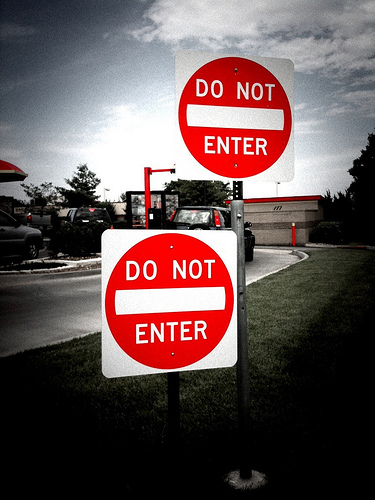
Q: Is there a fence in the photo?
A: No, there are no fences.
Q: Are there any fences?
A: No, there are no fences.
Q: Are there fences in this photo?
A: No, there are no fences.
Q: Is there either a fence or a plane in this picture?
A: No, there are no fences or airplanes.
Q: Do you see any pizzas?
A: No, there are no pizzas.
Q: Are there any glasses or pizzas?
A: No, there are no pizzas or glasses.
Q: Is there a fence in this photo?
A: No, there are no fences.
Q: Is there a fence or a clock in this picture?
A: No, there are no fences or clocks.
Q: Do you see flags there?
A: No, there are no flags.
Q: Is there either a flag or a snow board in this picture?
A: No, there are no flags or snowboards.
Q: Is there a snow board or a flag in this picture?
A: No, there are no flags or snowboards.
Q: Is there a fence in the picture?
A: No, there are no fences.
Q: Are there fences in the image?
A: No, there are no fences.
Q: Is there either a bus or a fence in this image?
A: No, there are no fences or buses.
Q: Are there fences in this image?
A: No, there are no fences.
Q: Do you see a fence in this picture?
A: No, there are no fences.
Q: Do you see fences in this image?
A: No, there are no fences.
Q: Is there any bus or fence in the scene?
A: No, there are no fences or buses.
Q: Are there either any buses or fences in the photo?
A: No, there are no fences or buses.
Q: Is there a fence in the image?
A: No, there are no fences.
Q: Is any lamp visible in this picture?
A: No, there are no lamps.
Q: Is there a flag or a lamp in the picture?
A: No, there are no lamps or flags.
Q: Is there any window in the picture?
A: Yes, there are windows.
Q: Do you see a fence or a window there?
A: Yes, there are windows.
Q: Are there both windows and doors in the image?
A: No, there are windows but no doors.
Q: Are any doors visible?
A: No, there are no doors.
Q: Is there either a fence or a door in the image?
A: No, there are no doors or fences.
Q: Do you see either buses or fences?
A: No, there are no fences or buses.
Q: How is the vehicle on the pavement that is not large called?
A: The vehicle is a car.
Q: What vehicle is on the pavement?
A: The vehicle is a car.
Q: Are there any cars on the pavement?
A: Yes, there is a car on the pavement.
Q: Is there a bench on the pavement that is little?
A: No, there is a car on the pavement.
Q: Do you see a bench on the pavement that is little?
A: No, there is a car on the pavement.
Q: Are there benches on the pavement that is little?
A: No, there is a car on the pavement.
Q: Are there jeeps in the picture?
A: No, there are no jeeps.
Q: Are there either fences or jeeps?
A: No, there are no jeeps or fences.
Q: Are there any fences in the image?
A: No, there are no fences.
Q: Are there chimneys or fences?
A: No, there are no fences or chimneys.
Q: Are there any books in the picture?
A: No, there are no books.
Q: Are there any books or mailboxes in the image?
A: No, there are no books or mailboxes.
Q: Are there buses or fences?
A: No, there are no fences or buses.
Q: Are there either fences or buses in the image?
A: No, there are no fences or buses.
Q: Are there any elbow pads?
A: No, there are no elbow pads.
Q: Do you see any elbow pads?
A: No, there are no elbow pads.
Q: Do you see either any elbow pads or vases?
A: No, there are no elbow pads or vases.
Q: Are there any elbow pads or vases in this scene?
A: No, there are no elbow pads or vases.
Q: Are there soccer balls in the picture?
A: No, there are no soccer balls.